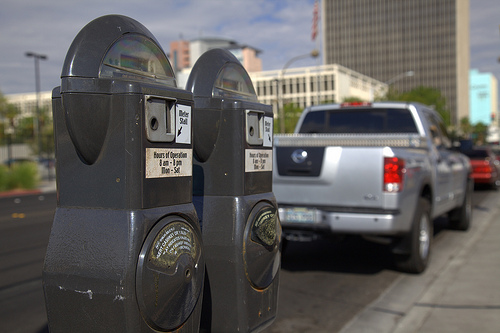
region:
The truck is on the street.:
[225, 87, 485, 282]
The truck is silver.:
[250, 85, 485, 279]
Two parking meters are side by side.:
[26, 13, 320, 331]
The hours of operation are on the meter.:
[130, 141, 206, 185]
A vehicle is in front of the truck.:
[447, 135, 497, 204]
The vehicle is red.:
[449, 140, 499, 192]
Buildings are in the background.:
[2, 0, 478, 123]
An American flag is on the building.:
[287, 2, 338, 73]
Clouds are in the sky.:
[0, 1, 310, 77]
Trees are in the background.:
[267, 77, 494, 147]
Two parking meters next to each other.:
[50, 11, 285, 331]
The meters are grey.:
[52, 5, 297, 331]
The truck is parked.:
[272, 94, 474, 280]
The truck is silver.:
[264, 95, 474, 265]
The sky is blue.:
[1, 1, 338, 81]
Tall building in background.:
[312, 2, 472, 137]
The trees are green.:
[0, 79, 495, 189]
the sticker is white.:
[167, 96, 197, 153]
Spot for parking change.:
[142, 89, 176, 141]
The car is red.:
[447, 135, 498, 186]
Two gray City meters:
[45, 8, 296, 328]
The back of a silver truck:
[275, 92, 449, 230]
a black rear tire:
[400, 191, 440, 272]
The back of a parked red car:
[467, 142, 497, 189]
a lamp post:
[16, 47, 53, 119]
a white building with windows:
[258, 58, 358, 114]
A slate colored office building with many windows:
[316, 0, 471, 76]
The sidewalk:
[397, 277, 497, 330]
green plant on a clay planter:
[1, 156, 51, 218]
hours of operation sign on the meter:
[143, 142, 198, 184]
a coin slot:
[158, 96, 179, 135]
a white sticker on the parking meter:
[141, 145, 198, 177]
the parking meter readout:
[111, 45, 157, 75]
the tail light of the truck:
[376, 152, 413, 199]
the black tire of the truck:
[388, 192, 443, 278]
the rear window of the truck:
[295, 104, 422, 142]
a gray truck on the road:
[265, 94, 482, 276]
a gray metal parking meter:
[31, 9, 213, 331]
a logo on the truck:
[288, 142, 318, 166]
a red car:
[454, 143, 496, 201]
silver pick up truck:
[274, 106, 479, 245]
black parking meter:
[57, 40, 280, 310]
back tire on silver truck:
[385, 180, 440, 261]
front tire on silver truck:
[452, 171, 477, 233]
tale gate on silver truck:
[277, 146, 409, 208]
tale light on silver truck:
[375, 145, 401, 205]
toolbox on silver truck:
[275, 131, 425, 147]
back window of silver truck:
[297, 105, 427, 133]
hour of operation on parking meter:
[140, 150, 203, 176]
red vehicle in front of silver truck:
[467, 151, 498, 193]